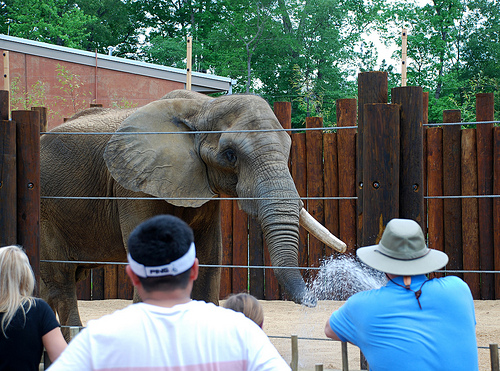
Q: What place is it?
A: It is a pen.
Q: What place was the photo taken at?
A: It was taken at the pen.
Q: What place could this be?
A: It is a pen.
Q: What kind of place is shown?
A: It is a pen.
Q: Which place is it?
A: It is a pen.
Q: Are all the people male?
A: No, they are both male and female.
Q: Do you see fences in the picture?
A: Yes, there is a fence.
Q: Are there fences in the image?
A: Yes, there is a fence.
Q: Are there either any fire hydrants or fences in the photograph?
A: Yes, there is a fence.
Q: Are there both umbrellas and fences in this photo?
A: No, there is a fence but no umbrellas.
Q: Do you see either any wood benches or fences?
A: Yes, there is a wood fence.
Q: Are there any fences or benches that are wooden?
A: Yes, the fence is wooden.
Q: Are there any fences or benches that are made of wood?
A: Yes, the fence is made of wood.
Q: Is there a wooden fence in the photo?
A: Yes, there is a wood fence.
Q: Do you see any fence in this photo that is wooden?
A: Yes, there is a fence that is wooden.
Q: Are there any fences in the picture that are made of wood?
A: Yes, there is a fence that is made of wood.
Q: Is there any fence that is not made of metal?
A: Yes, there is a fence that is made of wood.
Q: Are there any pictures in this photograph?
A: No, there are no pictures.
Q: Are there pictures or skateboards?
A: No, there are no pictures or skateboards.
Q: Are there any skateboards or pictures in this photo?
A: No, there are no pictures or skateboards.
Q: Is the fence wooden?
A: Yes, the fence is wooden.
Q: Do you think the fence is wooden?
A: Yes, the fence is wooden.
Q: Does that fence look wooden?
A: Yes, the fence is wooden.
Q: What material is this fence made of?
A: The fence is made of wood.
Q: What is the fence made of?
A: The fence is made of wood.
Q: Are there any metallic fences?
A: No, there is a fence but it is wooden.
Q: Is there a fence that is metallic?
A: No, there is a fence but it is wooden.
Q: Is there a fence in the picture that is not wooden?
A: No, there is a fence but it is wooden.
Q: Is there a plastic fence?
A: No, there is a fence but it is made of wood.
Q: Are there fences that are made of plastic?
A: No, there is a fence but it is made of wood.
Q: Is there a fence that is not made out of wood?
A: No, there is a fence but it is made of wood.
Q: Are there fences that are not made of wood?
A: No, there is a fence but it is made of wood.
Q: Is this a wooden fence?
A: Yes, this is a wooden fence.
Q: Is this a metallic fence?
A: No, this is a wooden fence.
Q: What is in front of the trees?
A: The fence is in front of the trees.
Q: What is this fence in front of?
A: The fence is in front of the trees.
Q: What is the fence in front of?
A: The fence is in front of the trees.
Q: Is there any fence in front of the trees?
A: Yes, there is a fence in front of the trees.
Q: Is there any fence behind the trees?
A: No, the fence is in front of the trees.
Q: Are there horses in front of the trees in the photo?
A: No, there is a fence in front of the trees.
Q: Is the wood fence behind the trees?
A: No, the fence is in front of the trees.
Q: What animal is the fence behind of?
A: The fence is behind the elephant.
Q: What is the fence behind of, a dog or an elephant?
A: The fence is behind an elephant.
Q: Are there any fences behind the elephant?
A: Yes, there is a fence behind the elephant.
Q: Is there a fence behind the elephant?
A: Yes, there is a fence behind the elephant.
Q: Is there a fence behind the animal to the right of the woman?
A: Yes, there is a fence behind the elephant.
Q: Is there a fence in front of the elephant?
A: No, the fence is behind the elephant.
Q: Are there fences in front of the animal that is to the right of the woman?
A: No, the fence is behind the elephant.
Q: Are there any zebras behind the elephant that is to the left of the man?
A: No, there is a fence behind the elephant.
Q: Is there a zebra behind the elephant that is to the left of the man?
A: No, there is a fence behind the elephant.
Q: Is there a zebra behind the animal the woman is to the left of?
A: No, there is a fence behind the elephant.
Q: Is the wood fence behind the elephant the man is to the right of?
A: Yes, the fence is behind the elephant.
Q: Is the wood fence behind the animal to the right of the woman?
A: Yes, the fence is behind the elephant.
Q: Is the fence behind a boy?
A: No, the fence is behind the elephant.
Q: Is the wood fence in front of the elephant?
A: No, the fence is behind the elephant.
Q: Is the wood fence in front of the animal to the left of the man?
A: No, the fence is behind the elephant.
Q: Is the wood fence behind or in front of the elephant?
A: The fence is behind the elephant.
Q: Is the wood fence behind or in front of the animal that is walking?
A: The fence is behind the elephant.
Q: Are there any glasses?
A: No, there are no glasses.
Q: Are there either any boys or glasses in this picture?
A: No, there are no glasses or boys.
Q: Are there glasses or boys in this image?
A: No, there are no glasses or boys.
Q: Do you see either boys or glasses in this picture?
A: No, there are no glasses or boys.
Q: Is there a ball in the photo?
A: No, there are no balls.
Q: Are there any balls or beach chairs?
A: No, there are no balls or beach chairs.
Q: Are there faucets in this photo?
A: No, there are no faucets.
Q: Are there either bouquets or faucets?
A: No, there are no faucets or bouquets.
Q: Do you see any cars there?
A: No, there are no cars.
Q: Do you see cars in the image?
A: No, there are no cars.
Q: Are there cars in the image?
A: No, there are no cars.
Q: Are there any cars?
A: No, there are no cars.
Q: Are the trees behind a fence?
A: Yes, the trees are behind a fence.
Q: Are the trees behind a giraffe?
A: No, the trees are behind a fence.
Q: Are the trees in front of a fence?
A: No, the trees are behind a fence.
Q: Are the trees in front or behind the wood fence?
A: The trees are behind the fence.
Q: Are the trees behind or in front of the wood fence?
A: The trees are behind the fence.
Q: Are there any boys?
A: No, there are no boys.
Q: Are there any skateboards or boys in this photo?
A: No, there are no boys or skateboards.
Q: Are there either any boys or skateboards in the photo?
A: No, there are no boys or skateboards.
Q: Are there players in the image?
A: No, there are no players.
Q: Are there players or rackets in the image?
A: No, there are no players or rackets.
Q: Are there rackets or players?
A: No, there are no players or rackets.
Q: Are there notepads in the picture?
A: No, there are no notepads.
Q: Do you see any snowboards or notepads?
A: No, there are no notepads or snowboards.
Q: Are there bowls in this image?
A: No, there are no bowls.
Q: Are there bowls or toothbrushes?
A: No, there are no bowls or toothbrushes.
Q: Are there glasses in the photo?
A: No, there are no glasses.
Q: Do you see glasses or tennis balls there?
A: No, there are no glasses or tennis balls.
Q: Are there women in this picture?
A: Yes, there is a woman.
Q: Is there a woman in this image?
A: Yes, there is a woman.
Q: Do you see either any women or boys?
A: Yes, there is a woman.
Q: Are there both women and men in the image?
A: Yes, there are both a woman and a man.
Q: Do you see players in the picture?
A: No, there are no players.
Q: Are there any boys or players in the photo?
A: No, there are no players or boys.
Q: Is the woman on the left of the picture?
A: Yes, the woman is on the left of the image.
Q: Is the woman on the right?
A: No, the woman is on the left of the image.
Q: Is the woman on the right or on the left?
A: The woman is on the left of the image.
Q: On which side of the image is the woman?
A: The woman is on the left of the image.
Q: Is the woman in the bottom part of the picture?
A: Yes, the woman is in the bottom of the image.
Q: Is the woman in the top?
A: No, the woman is in the bottom of the image.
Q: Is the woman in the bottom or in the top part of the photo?
A: The woman is in the bottom of the image.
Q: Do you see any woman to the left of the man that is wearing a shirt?
A: Yes, there is a woman to the left of the man.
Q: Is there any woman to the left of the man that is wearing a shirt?
A: Yes, there is a woman to the left of the man.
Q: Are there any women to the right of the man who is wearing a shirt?
A: No, the woman is to the left of the man.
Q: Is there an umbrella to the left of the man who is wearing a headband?
A: No, there is a woman to the left of the man.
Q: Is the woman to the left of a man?
A: Yes, the woman is to the left of a man.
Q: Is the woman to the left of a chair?
A: No, the woman is to the left of a man.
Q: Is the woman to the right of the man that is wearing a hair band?
A: No, the woman is to the left of the man.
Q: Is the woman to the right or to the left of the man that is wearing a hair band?
A: The woman is to the left of the man.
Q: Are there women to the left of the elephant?
A: Yes, there is a woman to the left of the elephant.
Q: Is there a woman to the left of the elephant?
A: Yes, there is a woman to the left of the elephant.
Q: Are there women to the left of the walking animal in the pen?
A: Yes, there is a woman to the left of the elephant.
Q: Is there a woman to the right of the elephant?
A: No, the woman is to the left of the elephant.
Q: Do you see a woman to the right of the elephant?
A: No, the woman is to the left of the elephant.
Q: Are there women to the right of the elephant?
A: No, the woman is to the left of the elephant.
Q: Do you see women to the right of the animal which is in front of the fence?
A: No, the woman is to the left of the elephant.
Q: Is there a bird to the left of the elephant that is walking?
A: No, there is a woman to the left of the elephant.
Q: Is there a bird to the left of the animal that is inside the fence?
A: No, there is a woman to the left of the elephant.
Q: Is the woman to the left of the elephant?
A: Yes, the woman is to the left of the elephant.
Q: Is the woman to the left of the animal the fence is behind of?
A: Yes, the woman is to the left of the elephant.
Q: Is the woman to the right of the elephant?
A: No, the woman is to the left of the elephant.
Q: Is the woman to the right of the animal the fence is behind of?
A: No, the woman is to the left of the elephant.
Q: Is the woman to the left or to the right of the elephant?
A: The woman is to the left of the elephant.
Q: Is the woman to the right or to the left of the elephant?
A: The woman is to the left of the elephant.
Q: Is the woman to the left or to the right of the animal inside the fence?
A: The woman is to the left of the elephant.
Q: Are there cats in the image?
A: No, there are no cats.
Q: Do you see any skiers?
A: No, there are no skiers.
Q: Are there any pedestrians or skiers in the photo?
A: No, there are no skiers or pedestrians.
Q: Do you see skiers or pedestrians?
A: No, there are no skiers or pedestrians.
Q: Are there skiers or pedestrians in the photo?
A: No, there are no skiers or pedestrians.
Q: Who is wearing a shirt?
A: The man is wearing a shirt.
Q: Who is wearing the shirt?
A: The man is wearing a shirt.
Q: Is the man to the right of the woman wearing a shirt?
A: Yes, the man is wearing a shirt.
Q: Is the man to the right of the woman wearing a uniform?
A: No, the man is wearing a shirt.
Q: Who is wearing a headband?
A: The man is wearing a headband.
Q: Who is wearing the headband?
A: The man is wearing a headband.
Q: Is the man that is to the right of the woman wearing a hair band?
A: Yes, the man is wearing a hair band.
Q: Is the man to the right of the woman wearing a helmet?
A: No, the man is wearing a hair band.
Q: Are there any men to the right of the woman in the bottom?
A: Yes, there is a man to the right of the woman.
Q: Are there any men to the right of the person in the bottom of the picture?
A: Yes, there is a man to the right of the woman.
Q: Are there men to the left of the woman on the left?
A: No, the man is to the right of the woman.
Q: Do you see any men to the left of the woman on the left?
A: No, the man is to the right of the woman.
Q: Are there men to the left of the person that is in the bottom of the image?
A: No, the man is to the right of the woman.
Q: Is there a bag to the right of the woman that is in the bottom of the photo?
A: No, there is a man to the right of the woman.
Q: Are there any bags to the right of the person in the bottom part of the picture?
A: No, there is a man to the right of the woman.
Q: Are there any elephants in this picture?
A: Yes, there is an elephant.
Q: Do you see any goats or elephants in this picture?
A: Yes, there is an elephant.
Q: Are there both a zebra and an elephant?
A: No, there is an elephant but no zebras.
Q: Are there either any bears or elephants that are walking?
A: Yes, the elephant is walking.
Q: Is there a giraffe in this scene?
A: No, there are no giraffes.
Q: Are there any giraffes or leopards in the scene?
A: No, there are no giraffes or leopards.